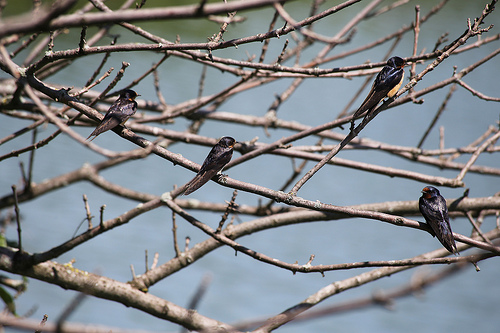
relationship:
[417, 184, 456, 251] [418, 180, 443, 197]
bird has bird head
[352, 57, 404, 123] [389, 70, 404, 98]
bird has underbelly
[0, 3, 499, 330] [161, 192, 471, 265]
tree has branch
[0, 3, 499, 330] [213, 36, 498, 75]
tree has branch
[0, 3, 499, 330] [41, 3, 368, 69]
tree has branch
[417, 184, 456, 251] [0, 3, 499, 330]
bird in tree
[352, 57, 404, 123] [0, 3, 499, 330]
bird in tree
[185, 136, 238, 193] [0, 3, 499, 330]
bird in tree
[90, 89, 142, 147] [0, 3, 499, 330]
bird in tree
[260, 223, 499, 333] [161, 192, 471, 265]
branch crosses branch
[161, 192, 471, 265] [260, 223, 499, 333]
branch crosses branch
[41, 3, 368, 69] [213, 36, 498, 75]
branch crosses branch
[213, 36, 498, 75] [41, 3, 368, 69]
branch crosses branch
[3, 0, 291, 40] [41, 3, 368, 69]
branch crosses branch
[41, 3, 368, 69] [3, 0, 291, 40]
branch crosses branch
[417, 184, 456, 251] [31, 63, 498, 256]
bird on branch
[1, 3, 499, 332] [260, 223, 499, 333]
sky behind branch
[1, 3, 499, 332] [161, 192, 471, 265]
sky behind branch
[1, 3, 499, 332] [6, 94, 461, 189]
sky behind branch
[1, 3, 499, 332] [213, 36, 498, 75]
sky behind branch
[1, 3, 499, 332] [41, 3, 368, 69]
sky behind branch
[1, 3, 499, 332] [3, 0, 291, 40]
sky behind branch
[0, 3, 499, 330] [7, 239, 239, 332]
tree has branch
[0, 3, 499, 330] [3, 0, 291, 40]
tree has branch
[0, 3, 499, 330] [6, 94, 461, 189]
tree has branch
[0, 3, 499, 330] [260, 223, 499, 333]
tree has branch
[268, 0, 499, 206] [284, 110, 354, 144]
bird with yellow chest perched on brown branch